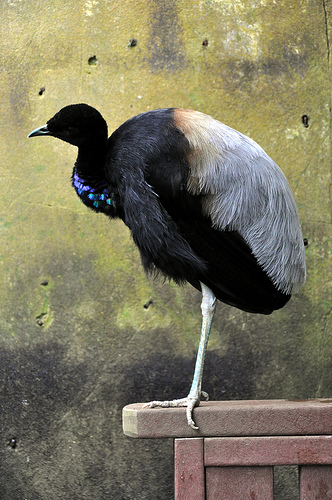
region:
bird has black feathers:
[134, 164, 288, 330]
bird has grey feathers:
[204, 141, 317, 299]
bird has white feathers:
[195, 108, 240, 155]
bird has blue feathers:
[69, 169, 119, 214]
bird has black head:
[45, 92, 109, 163]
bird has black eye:
[58, 116, 84, 140]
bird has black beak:
[22, 125, 54, 139]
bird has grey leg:
[141, 274, 226, 444]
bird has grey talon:
[141, 388, 219, 438]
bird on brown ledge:
[98, 360, 326, 497]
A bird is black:
[31, 102, 329, 312]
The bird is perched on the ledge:
[18, 100, 288, 414]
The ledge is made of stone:
[117, 411, 301, 459]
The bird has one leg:
[145, 276, 293, 480]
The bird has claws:
[132, 335, 233, 443]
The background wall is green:
[11, 188, 197, 394]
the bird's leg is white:
[144, 237, 326, 427]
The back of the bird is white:
[188, 131, 328, 284]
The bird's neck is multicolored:
[55, 168, 149, 226]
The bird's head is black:
[46, 109, 139, 147]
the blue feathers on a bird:
[70, 170, 120, 216]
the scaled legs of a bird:
[134, 281, 227, 433]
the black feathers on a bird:
[147, 180, 301, 338]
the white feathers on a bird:
[174, 104, 311, 303]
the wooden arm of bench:
[120, 396, 329, 498]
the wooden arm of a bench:
[110, 398, 328, 499]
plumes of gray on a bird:
[108, 104, 208, 297]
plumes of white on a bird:
[170, 102, 305, 299]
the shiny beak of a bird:
[27, 124, 49, 143]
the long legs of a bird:
[139, 268, 221, 434]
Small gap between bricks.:
[261, 462, 312, 498]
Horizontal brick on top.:
[203, 431, 329, 461]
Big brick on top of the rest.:
[122, 395, 326, 414]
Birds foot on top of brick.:
[147, 381, 247, 453]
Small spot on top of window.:
[36, 265, 59, 352]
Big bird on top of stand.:
[24, 70, 270, 437]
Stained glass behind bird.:
[18, 12, 311, 431]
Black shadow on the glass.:
[127, 16, 213, 99]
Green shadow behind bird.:
[9, 9, 127, 89]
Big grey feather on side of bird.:
[129, 170, 211, 296]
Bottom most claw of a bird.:
[191, 424, 198, 430]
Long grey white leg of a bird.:
[185, 276, 217, 397]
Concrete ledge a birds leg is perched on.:
[121, 399, 331, 436]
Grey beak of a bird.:
[27, 123, 49, 137]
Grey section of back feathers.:
[175, 107, 307, 294]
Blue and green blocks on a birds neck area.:
[72, 168, 115, 212]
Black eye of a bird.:
[66, 124, 73, 129]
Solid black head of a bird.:
[52, 103, 107, 145]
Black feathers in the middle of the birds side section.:
[148, 177, 292, 314]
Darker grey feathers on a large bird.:
[108, 107, 209, 281]